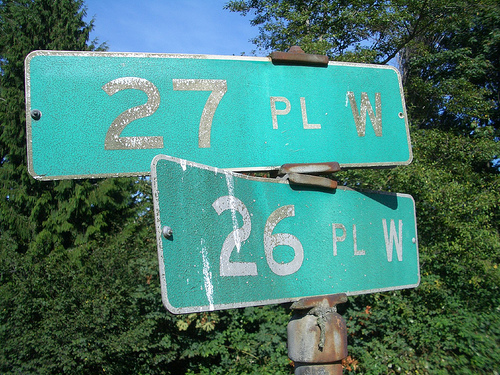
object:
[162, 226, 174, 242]
screw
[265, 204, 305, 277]
number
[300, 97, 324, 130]
letter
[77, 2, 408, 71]
blue sky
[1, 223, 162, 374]
trees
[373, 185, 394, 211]
ground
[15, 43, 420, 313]
markers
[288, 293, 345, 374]
pole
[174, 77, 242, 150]
number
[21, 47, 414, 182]
sign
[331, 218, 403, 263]
letters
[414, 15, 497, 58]
leaves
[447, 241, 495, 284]
leaves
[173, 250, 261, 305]
poop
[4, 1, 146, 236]
tree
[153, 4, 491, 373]
tree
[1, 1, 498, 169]
skies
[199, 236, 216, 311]
bird droppings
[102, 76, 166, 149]
number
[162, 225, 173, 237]
bolt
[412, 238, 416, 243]
bolt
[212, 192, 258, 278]
number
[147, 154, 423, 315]
sign